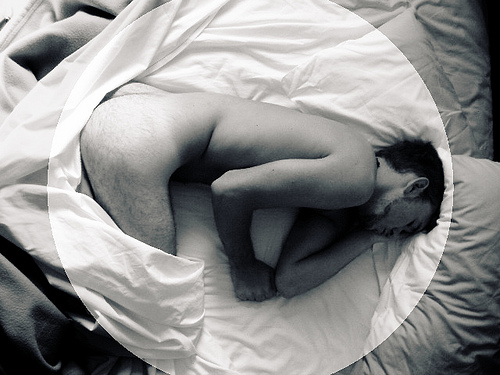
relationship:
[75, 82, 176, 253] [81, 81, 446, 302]
tan line on man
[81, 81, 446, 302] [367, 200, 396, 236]
man with beard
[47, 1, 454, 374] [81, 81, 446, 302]
circle under man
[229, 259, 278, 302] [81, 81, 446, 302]
hand of man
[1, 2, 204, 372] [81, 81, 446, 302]
sheet over man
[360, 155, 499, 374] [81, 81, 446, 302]
pillow near man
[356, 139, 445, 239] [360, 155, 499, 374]
head near pillow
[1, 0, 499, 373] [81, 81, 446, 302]
bed under man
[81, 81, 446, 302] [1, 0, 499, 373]
man on bed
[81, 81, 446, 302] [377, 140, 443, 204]
man has hair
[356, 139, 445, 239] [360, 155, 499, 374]
head on pillow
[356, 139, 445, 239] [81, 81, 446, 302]
head of man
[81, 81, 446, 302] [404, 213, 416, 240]
man with eyes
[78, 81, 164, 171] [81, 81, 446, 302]
butt of man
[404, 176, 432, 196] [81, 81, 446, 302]
ear of man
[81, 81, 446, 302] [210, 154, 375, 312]
man with arm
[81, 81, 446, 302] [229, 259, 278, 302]
man with hand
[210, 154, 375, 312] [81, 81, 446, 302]
arm of man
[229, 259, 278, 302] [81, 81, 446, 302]
hand on man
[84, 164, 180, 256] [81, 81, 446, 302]
leg of man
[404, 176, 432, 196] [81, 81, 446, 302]
ear on man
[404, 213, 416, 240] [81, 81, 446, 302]
eyes on man